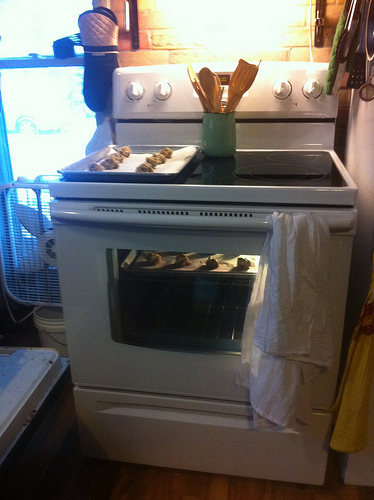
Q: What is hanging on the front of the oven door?
A: White towel.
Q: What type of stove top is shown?
A: Smooth top.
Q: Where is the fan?
A: Left side of the stove.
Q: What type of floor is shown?
A: Hardwood.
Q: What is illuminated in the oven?
A: Light.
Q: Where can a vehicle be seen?
A: Through the window.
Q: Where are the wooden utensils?
A: On the stove.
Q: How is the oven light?
A: On.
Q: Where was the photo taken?
A: In a kitchen.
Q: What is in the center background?
A: A bright light.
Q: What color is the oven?
A: White.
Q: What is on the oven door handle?
A: A white towel.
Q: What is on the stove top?
A: A tray of cookies.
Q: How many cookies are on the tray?
A: Eight.